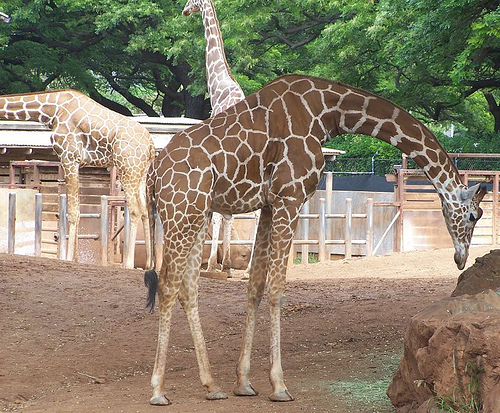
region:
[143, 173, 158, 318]
the giraffes long tail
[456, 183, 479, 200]
the giraffes white ear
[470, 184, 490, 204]
the hairy horns on the giraffes head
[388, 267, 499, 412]
a large boulder in the giraffe pen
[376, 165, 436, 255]
a wooden fence gate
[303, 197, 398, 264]
a wooden fence enclosure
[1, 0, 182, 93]
large trees behind the giraffe pen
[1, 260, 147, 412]
brown dirt ground along the giraffe pen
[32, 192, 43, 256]
a wood fence column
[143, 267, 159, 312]
long black hair on the tip of the tail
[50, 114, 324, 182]
Two giraffes back to back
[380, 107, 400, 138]
The arched neck of a giraffe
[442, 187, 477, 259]
Giraffe head facing down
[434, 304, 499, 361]
The surface of a rock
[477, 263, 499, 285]
Dark surface of the rock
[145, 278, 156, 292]
Black hairs on the tail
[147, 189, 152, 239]
Giraffe tail hanging down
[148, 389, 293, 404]
Four hooves on the ground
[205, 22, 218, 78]
The long neck of a giraffe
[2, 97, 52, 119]
Neck parallel to the ground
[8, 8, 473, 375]
There are three giraffes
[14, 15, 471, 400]
The giraffes are all standing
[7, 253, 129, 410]
The ground is covered in dirt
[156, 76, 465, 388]
Only the right side of this giraffe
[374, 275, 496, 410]
A large boulder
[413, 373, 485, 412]
Grass growing next to the boulder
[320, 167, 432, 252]
A fence around the animals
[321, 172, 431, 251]
The fence is made of wood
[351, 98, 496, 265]
The giraffes is bending its neck down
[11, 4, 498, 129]
Trees outside of the enclosed area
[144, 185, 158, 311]
the tail of a girafffe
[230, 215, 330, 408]
the fore legs of a giraffe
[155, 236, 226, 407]
the behind legs of a giraffe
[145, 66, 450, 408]
a tall giraffe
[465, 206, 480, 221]
the eye of a giraffe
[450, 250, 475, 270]
the mouth of a giraffe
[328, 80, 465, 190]
the long neck of a giraffe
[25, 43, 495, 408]
three giraffes standing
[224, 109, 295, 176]
pattern on side of giraffe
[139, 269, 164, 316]
black hair on end of giraffe tail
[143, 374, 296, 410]
hooves on feet of giraffe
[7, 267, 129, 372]
ground covered in brown dirt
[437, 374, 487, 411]
small green plant growing beside rock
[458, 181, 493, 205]
small horns on head of giraffe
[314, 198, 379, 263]
brown wooden fencing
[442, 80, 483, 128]
green leaves on the tree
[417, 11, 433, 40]
green leaves on the tree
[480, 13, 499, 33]
green leaves on the tree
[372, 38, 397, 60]
green leaves on the tree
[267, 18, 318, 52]
green leaves on the tree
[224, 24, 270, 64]
green leaves on the tree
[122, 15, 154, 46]
green leaves on the tree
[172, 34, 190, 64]
green leaves on the tree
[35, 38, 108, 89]
green leaves on the tree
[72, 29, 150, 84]
green leaves on the tree